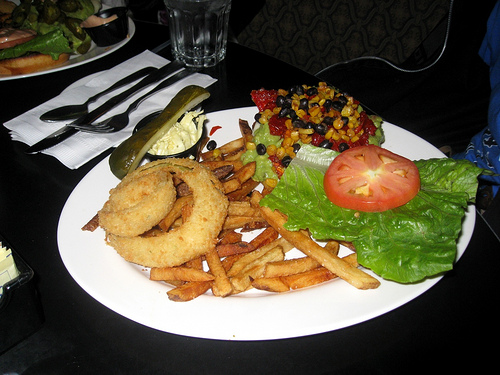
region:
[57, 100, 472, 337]
food on a white plate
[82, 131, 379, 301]
french fries on the left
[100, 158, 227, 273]
onion rings on top of french fries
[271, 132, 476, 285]
a piece of lettuce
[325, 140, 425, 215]
a tomato on top of the lettuce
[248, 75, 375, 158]
corn, black bean salad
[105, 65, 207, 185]
a pickle on top of a container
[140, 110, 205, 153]
container holding a condiment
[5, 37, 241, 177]
white napkin with silverware on top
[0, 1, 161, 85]
a plate of food in upper left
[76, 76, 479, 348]
a plate of food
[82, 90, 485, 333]
plate on the table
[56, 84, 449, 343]
the plate is white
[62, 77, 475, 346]
the plate is round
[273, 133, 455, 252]
lettuce and tomato on the plate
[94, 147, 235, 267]
an onion ring on the plate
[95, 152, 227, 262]
the onion ring is golden brown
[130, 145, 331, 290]
french fries under the onion rings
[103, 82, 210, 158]
a pickle on the cole slaw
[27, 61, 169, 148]
utensils on a napkin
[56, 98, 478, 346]
Food on a plate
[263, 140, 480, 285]
Slice of tomato on a piece of lettuce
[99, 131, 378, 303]
Onion rings on top of French fries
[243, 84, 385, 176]
Corn and bean salad on top of guacamole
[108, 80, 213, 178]
Slice of pickle on top of butter tub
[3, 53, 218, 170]
Silverware on a napkin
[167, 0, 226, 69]
Empty glass on the table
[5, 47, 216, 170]
Napkin under the silverware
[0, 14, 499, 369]
Black table top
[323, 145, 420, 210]
Slice of tomato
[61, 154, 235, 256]
onion rings on white plate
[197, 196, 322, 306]
french fries on white plate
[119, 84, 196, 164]
pickle on white plate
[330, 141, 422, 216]
sliced tomato on plate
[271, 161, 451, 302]
green lettuce on plate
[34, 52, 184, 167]
utensils on white napkin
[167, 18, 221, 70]
water glass by napkin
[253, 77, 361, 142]
corn and beans on plate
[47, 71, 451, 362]
white plate on dark surface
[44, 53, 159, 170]
napkins on dark surface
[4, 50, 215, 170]
white paper napkin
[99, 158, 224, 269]
onion rings on plate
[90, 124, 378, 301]
french fries on plate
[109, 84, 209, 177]
pickle balanced on black ramekin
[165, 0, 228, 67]
clear glass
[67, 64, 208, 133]
silver fork on napkin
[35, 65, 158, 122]
silver spoon on napkin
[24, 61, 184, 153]
silver knife on napkin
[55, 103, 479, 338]
round white plate with fries and other food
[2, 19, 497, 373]
black table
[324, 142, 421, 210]
Tomato on the plate.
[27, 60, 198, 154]
Silverware on the table.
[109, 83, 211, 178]
Pickle on the plate.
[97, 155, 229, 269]
Onion rings on the plate.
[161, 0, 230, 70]
Glass on the table.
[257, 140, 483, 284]
slice of tomato on top of lettuce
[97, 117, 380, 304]
onion rings over french fries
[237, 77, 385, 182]
bean and corn over lettuce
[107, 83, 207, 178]
pickle laying over coleslaw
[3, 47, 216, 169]
silverware over white paper napkin